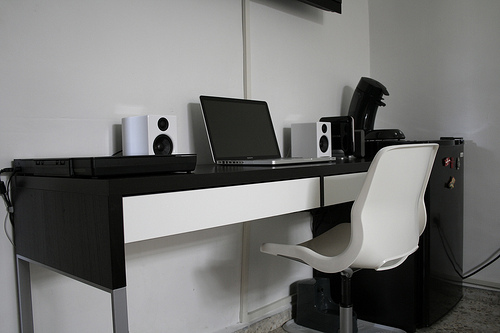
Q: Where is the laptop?
A: Desk.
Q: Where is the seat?
A: In front of the desk.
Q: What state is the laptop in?
A: Turned off.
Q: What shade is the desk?
A: Black.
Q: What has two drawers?
A: The desk.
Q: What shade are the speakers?
A: White.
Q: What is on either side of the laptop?
A: Speakers.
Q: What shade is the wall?
A: White.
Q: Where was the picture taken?
A: Office.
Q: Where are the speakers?
A: By the laptop.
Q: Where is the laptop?
A: On the desk.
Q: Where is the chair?
A: By the desk.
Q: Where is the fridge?
A: In the corner.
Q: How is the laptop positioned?
A: Open.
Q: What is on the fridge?
A: Magnets.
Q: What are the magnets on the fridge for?
A: Decoration.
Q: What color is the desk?
A: Black and white.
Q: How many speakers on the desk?
A: Two.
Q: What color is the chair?
A: White.